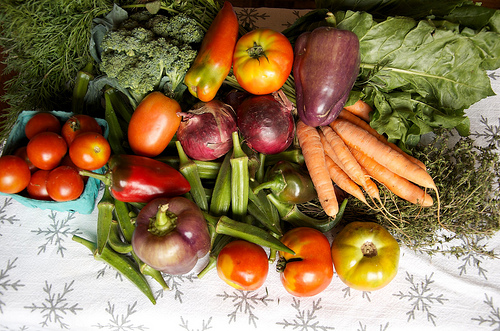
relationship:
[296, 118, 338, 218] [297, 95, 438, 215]
carrot in bundle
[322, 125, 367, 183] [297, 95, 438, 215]
carrot in bundle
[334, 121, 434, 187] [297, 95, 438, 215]
carrot in bundle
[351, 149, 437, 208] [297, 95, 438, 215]
carrot in bundle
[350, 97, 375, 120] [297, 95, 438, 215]
carrot in bundle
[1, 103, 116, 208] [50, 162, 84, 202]
container has tomato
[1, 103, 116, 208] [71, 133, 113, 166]
container has tomato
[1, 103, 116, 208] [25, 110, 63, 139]
container has tomato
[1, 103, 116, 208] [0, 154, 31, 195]
container has tomato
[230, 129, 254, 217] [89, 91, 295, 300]
okra in pile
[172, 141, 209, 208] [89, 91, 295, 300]
okra in pile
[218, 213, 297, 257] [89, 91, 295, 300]
okra in pile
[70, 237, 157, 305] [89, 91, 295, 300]
okra in pile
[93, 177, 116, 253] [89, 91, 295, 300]
okra in pile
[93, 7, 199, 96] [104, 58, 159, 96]
broccoli has stalk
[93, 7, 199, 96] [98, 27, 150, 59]
broccoli has stalk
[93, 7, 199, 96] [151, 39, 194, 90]
broccoli has stalk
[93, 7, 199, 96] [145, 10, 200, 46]
broccoli has stalk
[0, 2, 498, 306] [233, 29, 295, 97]
garden has tomato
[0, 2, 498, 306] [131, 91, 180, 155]
garden has tomato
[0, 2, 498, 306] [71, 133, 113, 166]
garden has tomato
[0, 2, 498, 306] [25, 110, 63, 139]
garden has tomato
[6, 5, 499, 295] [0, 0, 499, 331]
vegetables are in photo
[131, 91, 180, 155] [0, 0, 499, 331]
tomato in photo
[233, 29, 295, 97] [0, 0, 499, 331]
tomato in photo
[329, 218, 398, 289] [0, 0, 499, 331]
vegetables in photo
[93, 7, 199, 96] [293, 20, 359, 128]
broccoli near pepper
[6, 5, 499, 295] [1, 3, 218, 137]
vegetables are on left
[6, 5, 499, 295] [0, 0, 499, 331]
vegetables are on photo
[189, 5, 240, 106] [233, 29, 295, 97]
pepper next to tomato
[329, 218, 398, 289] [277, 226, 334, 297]
vegetables next tomato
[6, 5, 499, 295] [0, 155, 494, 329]
vegetables are on top of table cloth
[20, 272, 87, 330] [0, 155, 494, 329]
snowflakes on top of table cloth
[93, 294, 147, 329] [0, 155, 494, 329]
snowflakes on top of table cloth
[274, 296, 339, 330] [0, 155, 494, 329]
snowflakes on top of table cloth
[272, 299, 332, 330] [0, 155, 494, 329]
snowflakes on top of table cloth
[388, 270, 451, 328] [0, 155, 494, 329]
snowflakes on top of table cloth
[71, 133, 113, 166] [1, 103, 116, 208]
tomato inside container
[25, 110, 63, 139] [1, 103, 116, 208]
tomato inside container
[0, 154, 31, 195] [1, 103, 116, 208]
tomato inside container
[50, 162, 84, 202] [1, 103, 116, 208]
tomato inside container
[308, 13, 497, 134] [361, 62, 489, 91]
vegetable has vein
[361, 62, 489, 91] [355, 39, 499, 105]
vein in middle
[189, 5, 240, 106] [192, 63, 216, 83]
jalapeno has spot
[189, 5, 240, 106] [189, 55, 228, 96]
jalapeno has spot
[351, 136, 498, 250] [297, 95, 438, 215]
thyme herb in bundle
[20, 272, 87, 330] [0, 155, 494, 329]
snowflakes in table cloth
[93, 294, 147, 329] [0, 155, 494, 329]
snowflakes in table cloth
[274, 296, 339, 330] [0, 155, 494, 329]
snowflakes in table cloth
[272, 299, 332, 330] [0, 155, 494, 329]
snowflakes in table cloth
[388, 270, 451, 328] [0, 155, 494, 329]
snowflakes in table cloth